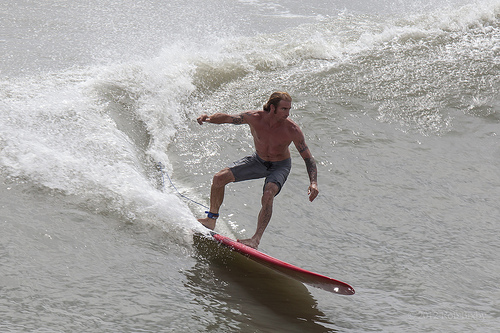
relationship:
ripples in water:
[9, 194, 216, 326] [1, 3, 497, 330]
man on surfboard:
[195, 91, 319, 249] [207, 229, 355, 294]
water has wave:
[55, 30, 155, 133] [343, 17, 444, 126]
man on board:
[175, 94, 327, 239] [210, 230, 355, 295]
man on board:
[195, 91, 319, 249] [184, 206, 360, 303]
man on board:
[195, 91, 319, 249] [200, 225, 359, 300]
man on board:
[195, 91, 319, 249] [172, 194, 374, 331]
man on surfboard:
[195, 91, 319, 249] [180, 187, 347, 332]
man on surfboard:
[195, 91, 319, 249] [208, 233, 359, 300]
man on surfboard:
[195, 91, 319, 249] [214, 226, 360, 299]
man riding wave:
[195, 91, 319, 249] [2, 28, 182, 208]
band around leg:
[205, 211, 220, 219] [195, 160, 259, 227]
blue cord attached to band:
[155, 162, 209, 209] [203, 210, 219, 219]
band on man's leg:
[203, 210, 219, 219] [195, 157, 264, 229]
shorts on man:
[226, 153, 291, 195] [195, 91, 319, 249]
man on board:
[195, 91, 319, 249] [210, 230, 355, 295]